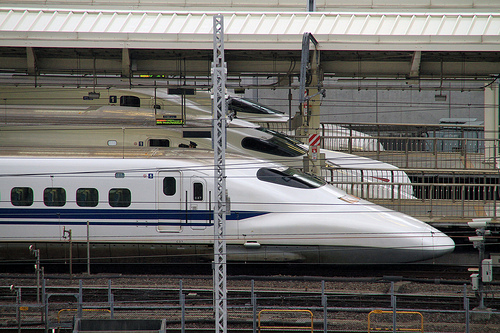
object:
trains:
[0, 119, 425, 199]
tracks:
[0, 255, 497, 280]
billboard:
[155, 119, 185, 125]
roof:
[0, 0, 500, 52]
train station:
[0, 0, 500, 333]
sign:
[307, 133, 322, 147]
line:
[0, 207, 271, 226]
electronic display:
[156, 118, 184, 125]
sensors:
[480, 260, 491, 284]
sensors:
[467, 265, 479, 294]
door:
[182, 170, 208, 232]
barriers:
[316, 153, 498, 216]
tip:
[387, 214, 453, 259]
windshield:
[254, 165, 328, 190]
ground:
[356, 136, 372, 181]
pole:
[204, 10, 236, 305]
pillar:
[208, 10, 229, 333]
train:
[2, 85, 387, 154]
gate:
[328, 178, 485, 226]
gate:
[293, 164, 484, 200]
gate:
[284, 132, 484, 170]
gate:
[285, 132, 485, 154]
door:
[155, 169, 185, 233]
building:
[1, 1, 484, 177]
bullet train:
[1, 153, 456, 268]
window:
[10, 186, 35, 205]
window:
[43, 187, 65, 207]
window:
[76, 188, 98, 206]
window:
[109, 189, 131, 206]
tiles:
[1, 0, 498, 52]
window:
[163, 175, 176, 196]